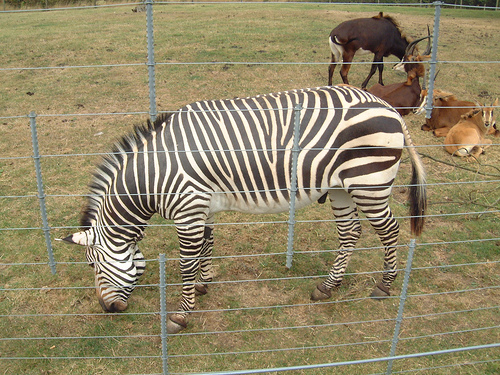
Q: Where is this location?
A: Pen.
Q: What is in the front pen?
A: Zebra.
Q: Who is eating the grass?
A: Animals.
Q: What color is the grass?
A: Green.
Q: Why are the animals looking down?
A: Eating.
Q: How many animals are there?
A: Five.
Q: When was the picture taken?
A: Daytime.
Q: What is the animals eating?
A: Grass.